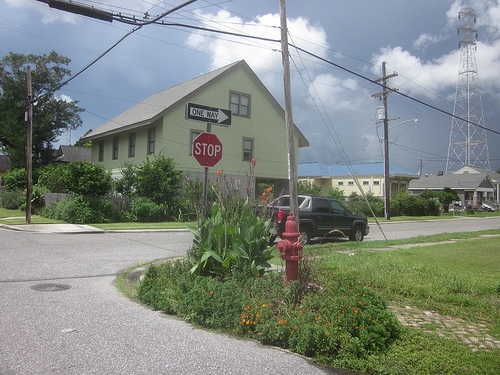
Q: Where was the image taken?
A: It was taken at the road.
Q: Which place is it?
A: It is a road.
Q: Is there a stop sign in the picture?
A: Yes, there is a stop sign.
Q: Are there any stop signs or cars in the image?
A: Yes, there is a stop sign.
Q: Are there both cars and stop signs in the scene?
A: Yes, there are both a stop sign and a car.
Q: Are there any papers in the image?
A: No, there are no papers.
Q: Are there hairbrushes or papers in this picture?
A: No, there are no papers or hairbrushes.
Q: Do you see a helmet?
A: No, there are no helmets.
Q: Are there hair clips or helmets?
A: No, there are no helmets or hair clips.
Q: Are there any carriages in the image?
A: No, there are no carriages.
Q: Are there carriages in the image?
A: No, there are no carriages.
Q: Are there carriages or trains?
A: No, there are no carriages or trains.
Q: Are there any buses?
A: No, there are no buses.